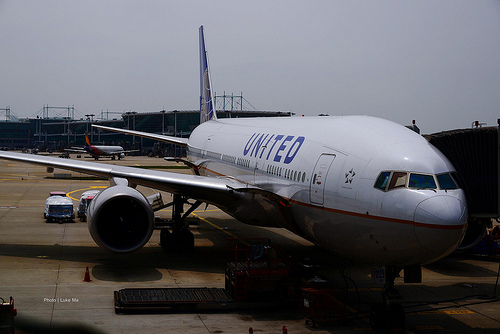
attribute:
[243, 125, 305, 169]
words — blue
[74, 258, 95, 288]
orange cone —  orange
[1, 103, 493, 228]
building —  big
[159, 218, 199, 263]
wheels —   of aircraft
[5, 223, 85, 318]
floor — cement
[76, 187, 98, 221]
truck — white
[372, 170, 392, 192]
window — blue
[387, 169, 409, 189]
window — blue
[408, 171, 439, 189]
window — blue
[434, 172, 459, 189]
window — blue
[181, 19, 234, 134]
plane tail — blue, red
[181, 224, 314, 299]
truck — red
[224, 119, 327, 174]
words — blue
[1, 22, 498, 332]
plane — white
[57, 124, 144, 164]
airplane — white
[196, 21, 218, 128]
tail —  tall ,  of aircraft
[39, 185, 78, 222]
cart — of stuff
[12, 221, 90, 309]
floor — brown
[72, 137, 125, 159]
plane — white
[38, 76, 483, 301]
plane — white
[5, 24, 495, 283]
plane — white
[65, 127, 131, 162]
plane — white, orange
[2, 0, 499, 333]
airport —  beautiful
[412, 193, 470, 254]
nose —  with different colors,  aircraft's